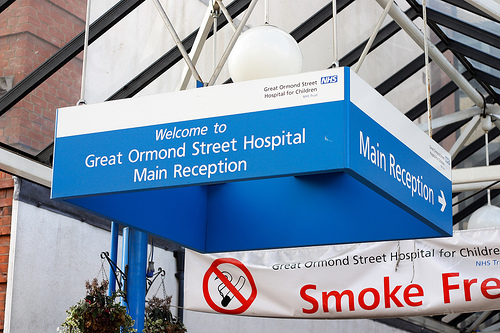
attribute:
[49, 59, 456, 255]
sign —  blue and white, one,  hospital's,  hanging, to welcome, of direction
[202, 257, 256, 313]
symbol —   banner's,  for no smoking ,  banner's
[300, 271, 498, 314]
smoke free —  in red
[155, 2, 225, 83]
framework —  metal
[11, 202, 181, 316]
tarp —  white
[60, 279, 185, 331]
baskets —  two,  of flower,  hanging 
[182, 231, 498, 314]
banner —  about smoking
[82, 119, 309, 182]
words —  welcoming,  sign's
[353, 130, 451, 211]
direction —  to reception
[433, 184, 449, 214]
arrow —  white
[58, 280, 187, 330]
pots —  two,  hanging,  flower's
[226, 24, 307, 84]
light —  white,   round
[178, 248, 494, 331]
wall —  brick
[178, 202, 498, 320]
sign —  white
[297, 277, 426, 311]
writing —  red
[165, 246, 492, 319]
sign — white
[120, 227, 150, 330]
pole — blue, one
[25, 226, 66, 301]
wall — one, gray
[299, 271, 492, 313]
letters — red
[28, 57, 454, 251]
box — one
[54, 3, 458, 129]
poles — some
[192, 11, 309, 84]
globe — light, round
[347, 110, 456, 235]
letters — white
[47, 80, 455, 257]
sign — one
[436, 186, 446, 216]
arrow — one, white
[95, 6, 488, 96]
panels — glass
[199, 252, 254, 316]
circle — red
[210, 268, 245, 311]
cigarette — one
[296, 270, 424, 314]
word —  smoke , red letters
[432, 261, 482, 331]
letters — Fre, red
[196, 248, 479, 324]
sign —  no smoking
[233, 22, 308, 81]
light —  large , circular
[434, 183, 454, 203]
arrow — white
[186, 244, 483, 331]
banner — white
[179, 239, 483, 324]
banner — no smoking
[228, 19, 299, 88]
light — hanging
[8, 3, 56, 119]
wall — brick 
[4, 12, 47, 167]
wall — brick 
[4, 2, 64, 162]
wall — brick 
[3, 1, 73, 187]
wall — brick 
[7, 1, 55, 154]
wall — brick 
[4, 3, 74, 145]
wall — brick 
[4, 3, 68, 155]
wall — brick 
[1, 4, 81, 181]
wall — brick 